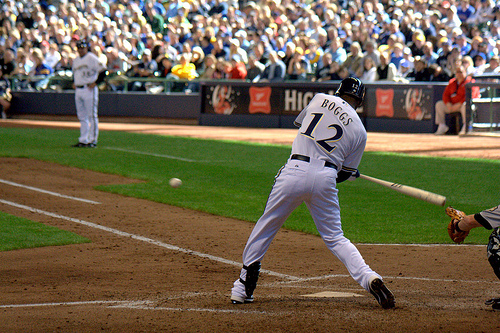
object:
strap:
[239, 262, 247, 269]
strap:
[236, 275, 247, 285]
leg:
[238, 195, 304, 281]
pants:
[73, 85, 104, 146]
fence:
[1, 78, 500, 135]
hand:
[333, 169, 351, 183]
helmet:
[332, 76, 367, 103]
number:
[315, 123, 345, 155]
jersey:
[290, 88, 370, 175]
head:
[335, 75, 366, 111]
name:
[319, 99, 352, 126]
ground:
[0, 117, 499, 333]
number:
[355, 84, 359, 90]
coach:
[69, 37, 108, 149]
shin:
[331, 239, 374, 293]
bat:
[358, 173, 447, 208]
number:
[300, 112, 325, 141]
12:
[299, 112, 346, 155]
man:
[67, 37, 107, 153]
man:
[429, 63, 480, 136]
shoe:
[367, 277, 397, 310]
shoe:
[230, 289, 253, 307]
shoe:
[70, 141, 89, 149]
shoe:
[431, 126, 456, 136]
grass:
[0, 120, 499, 246]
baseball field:
[0, 117, 499, 332]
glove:
[442, 206, 474, 245]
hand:
[445, 214, 470, 245]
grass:
[0, 210, 94, 253]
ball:
[164, 176, 183, 188]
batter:
[227, 76, 398, 311]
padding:
[238, 261, 261, 298]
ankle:
[360, 285, 371, 291]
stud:
[390, 298, 392, 301]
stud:
[391, 302, 394, 305]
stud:
[380, 298, 383, 300]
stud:
[380, 280, 382, 283]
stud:
[373, 285, 376, 288]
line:
[353, 239, 485, 247]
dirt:
[1, 152, 500, 333]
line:
[0, 296, 146, 309]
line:
[0, 199, 301, 281]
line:
[0, 179, 106, 206]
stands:
[0, 0, 499, 134]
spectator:
[170, 51, 199, 80]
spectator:
[225, 50, 249, 82]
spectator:
[260, 48, 287, 79]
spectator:
[132, 47, 159, 78]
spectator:
[370, 49, 398, 81]